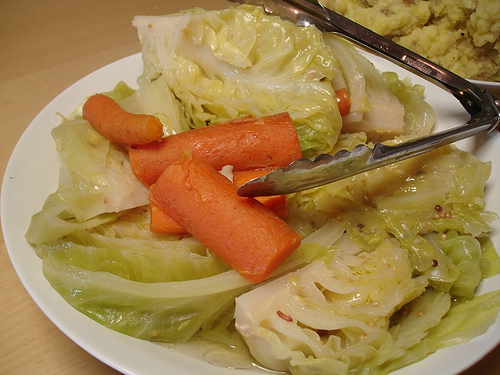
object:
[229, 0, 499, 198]
tong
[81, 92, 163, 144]
carrot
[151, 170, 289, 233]
carrot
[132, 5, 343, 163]
cabbage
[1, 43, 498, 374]
plate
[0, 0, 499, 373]
table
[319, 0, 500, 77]
bowl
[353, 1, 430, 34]
cauliflower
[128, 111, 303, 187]
carrot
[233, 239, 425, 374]
cabbage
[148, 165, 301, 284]
carrot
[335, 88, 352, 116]
carrot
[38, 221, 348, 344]
cabbage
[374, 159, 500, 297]
cabbage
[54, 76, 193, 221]
cabbage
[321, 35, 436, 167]
cabbage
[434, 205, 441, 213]
spice